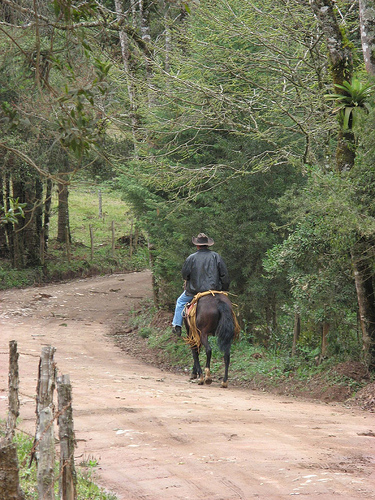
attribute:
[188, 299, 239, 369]
horse — black, tall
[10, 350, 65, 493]
fence — wooden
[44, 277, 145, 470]
road — dirt, dirty, unpaved, rocky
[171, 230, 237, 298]
man — on horse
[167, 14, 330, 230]
tree — green, tall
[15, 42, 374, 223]
trees — green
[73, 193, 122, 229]
grass — green